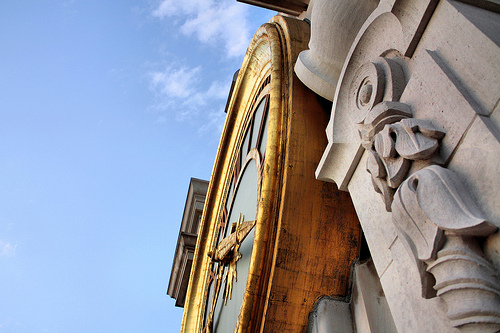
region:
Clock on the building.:
[111, 71, 413, 331]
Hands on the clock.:
[156, 212, 308, 294]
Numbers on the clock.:
[196, 127, 282, 188]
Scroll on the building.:
[287, 22, 498, 323]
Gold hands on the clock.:
[196, 188, 277, 290]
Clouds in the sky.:
[139, 4, 331, 152]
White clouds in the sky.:
[136, 39, 235, 128]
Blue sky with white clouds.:
[121, 6, 270, 173]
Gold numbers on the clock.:
[189, 123, 285, 205]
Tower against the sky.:
[133, 135, 254, 292]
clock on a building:
[7, 5, 495, 328]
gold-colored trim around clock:
[173, 30, 299, 326]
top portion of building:
[165, 175, 212, 310]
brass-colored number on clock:
[214, 195, 234, 230]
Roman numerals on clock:
[216, 140, 245, 231]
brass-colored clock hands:
[204, 214, 263, 327]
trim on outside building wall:
[351, 98, 495, 329]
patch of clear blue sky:
[7, 5, 136, 206]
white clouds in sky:
[143, 3, 220, 128]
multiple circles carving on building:
[343, 53, 409, 124]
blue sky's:
[63, 35, 131, 100]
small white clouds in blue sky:
[150, 8, 236, 49]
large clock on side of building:
[165, 17, 370, 329]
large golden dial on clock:
[198, 205, 263, 261]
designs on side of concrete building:
[315, 27, 496, 288]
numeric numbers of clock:
[217, 110, 273, 170]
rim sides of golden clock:
[272, 215, 348, 290]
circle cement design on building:
[336, 62, 396, 115]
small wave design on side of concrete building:
[358, 107, 439, 172]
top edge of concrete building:
[146, 180, 203, 290]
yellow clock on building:
[194, 131, 298, 316]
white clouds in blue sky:
[14, 13, 112, 91]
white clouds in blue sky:
[125, 6, 207, 84]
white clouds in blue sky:
[12, 51, 116, 143]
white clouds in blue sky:
[131, 78, 213, 152]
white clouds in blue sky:
[14, 115, 86, 183]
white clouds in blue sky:
[102, 109, 177, 214]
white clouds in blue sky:
[22, 192, 124, 277]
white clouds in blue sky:
[82, 19, 189, 114]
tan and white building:
[365, 51, 493, 215]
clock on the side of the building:
[134, 31, 346, 332]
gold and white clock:
[149, 21, 377, 331]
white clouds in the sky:
[143, 5, 268, 117]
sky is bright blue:
[1, 2, 243, 332]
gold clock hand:
[205, 218, 258, 263]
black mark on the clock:
[276, 284, 296, 303]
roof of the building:
[146, 173, 218, 318]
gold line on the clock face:
[242, 116, 256, 153]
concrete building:
[267, 3, 499, 330]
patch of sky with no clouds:
[35, 138, 110, 220]